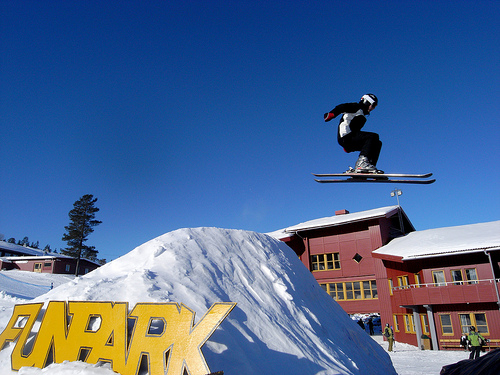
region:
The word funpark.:
[3, 300, 230, 374]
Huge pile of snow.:
[71, 224, 403, 373]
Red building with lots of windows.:
[268, 206, 498, 350]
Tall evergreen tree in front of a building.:
[58, 190, 93, 280]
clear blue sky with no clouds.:
[11, 5, 291, 195]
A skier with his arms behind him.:
[313, 80, 445, 196]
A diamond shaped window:
[341, 249, 366, 270]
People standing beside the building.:
[378, 321, 487, 353]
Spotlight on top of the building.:
[390, 186, 406, 213]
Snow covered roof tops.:
[266, 202, 498, 267]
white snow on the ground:
[398, 350, 435, 355]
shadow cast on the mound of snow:
[203, 290, 318, 350]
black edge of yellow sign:
[119, 279, 249, 333]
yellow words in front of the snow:
[35, 282, 217, 373]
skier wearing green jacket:
[438, 324, 494, 346]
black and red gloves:
[293, 89, 349, 128]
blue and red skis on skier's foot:
[279, 152, 449, 185]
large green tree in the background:
[52, 181, 112, 262]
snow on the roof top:
[347, 217, 472, 284]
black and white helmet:
[341, 83, 401, 111]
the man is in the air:
[275, 87, 443, 198]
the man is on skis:
[297, 92, 472, 193]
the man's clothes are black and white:
[310, 72, 412, 160]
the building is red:
[282, 220, 497, 342]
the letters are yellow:
[5, 287, 233, 372]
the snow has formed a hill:
[60, 210, 371, 374]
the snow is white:
[58, 210, 472, 357]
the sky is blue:
[1, 1, 479, 172]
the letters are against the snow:
[2, 294, 239, 372]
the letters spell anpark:
[2, 288, 229, 372]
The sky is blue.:
[41, 12, 241, 142]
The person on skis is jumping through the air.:
[298, 75, 450, 195]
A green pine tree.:
[43, 182, 114, 274]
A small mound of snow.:
[40, 183, 362, 351]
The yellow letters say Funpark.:
[1, 275, 226, 373]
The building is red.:
[260, 188, 496, 351]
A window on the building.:
[436, 306, 454, 339]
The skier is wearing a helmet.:
[358, 82, 380, 112]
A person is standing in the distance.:
[450, 317, 487, 359]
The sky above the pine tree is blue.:
[36, 117, 138, 237]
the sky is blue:
[90, 72, 267, 163]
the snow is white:
[138, 239, 313, 308]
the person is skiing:
[293, 70, 470, 228]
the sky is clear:
[87, 65, 239, 167]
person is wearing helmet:
[348, 90, 394, 129]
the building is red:
[303, 228, 408, 346]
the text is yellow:
[0, 287, 230, 374]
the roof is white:
[365, 202, 487, 272]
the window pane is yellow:
[311, 270, 380, 298]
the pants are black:
[321, 126, 393, 163]